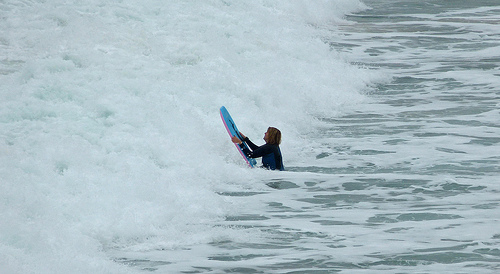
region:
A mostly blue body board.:
[218, 106, 259, 168]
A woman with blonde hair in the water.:
[231, 127, 285, 172]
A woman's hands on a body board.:
[231, 128, 246, 143]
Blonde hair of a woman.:
[265, 123, 282, 144]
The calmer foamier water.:
[317, 1, 498, 273]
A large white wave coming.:
[0, 2, 271, 273]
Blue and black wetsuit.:
[240, 135, 285, 173]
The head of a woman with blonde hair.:
[263, 125, 282, 145]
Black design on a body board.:
[227, 117, 242, 141]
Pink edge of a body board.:
[216, 112, 250, 167]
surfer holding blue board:
[208, 98, 308, 199]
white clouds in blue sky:
[29, 10, 89, 55]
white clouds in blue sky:
[50, 40, 92, 80]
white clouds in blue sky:
[13, 55, 43, 77]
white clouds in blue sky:
[56, 86, 73, 104]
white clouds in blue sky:
[22, 122, 62, 154]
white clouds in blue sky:
[74, 40, 101, 74]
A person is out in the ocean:
[25, 21, 490, 261]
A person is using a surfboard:
[35, 33, 482, 261]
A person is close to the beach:
[21, 27, 456, 272]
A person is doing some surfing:
[32, 26, 463, 252]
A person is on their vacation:
[20, 18, 485, 269]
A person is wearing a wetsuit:
[36, 23, 474, 263]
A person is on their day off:
[30, 16, 472, 266]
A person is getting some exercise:
[35, 31, 486, 256]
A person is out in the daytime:
[26, 37, 446, 249]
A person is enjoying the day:
[30, 37, 412, 255]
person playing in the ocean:
[205, 92, 306, 202]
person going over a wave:
[202, 103, 294, 200]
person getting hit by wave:
[191, 108, 296, 190]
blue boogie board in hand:
[217, 102, 259, 160]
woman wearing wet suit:
[252, 128, 290, 170]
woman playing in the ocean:
[194, 92, 302, 224]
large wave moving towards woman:
[98, 75, 253, 205]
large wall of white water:
[20, 101, 168, 232]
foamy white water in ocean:
[365, 92, 443, 190]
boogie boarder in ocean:
[211, 99, 296, 187]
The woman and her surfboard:
[201, 100, 291, 183]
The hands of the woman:
[228, 130, 249, 145]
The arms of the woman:
[238, 133, 268, 163]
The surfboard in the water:
[209, 103, 258, 168]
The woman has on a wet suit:
[236, 123, 297, 173]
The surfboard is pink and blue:
[216, 97, 261, 173]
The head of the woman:
[261, 120, 284, 147]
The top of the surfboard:
[217, 98, 243, 139]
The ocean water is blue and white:
[303, 18, 498, 271]